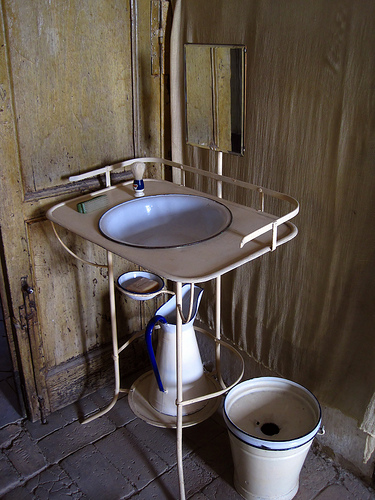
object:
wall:
[187, 1, 371, 378]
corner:
[158, 6, 196, 324]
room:
[0, 1, 375, 500]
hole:
[259, 422, 281, 437]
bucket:
[222, 376, 320, 500]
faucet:
[130, 162, 145, 198]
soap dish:
[117, 270, 165, 301]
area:
[180, 0, 373, 221]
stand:
[47, 154, 302, 495]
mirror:
[181, 43, 245, 154]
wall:
[2, 0, 175, 431]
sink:
[98, 191, 234, 245]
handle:
[140, 314, 168, 395]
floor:
[0, 363, 374, 499]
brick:
[0, 479, 37, 500]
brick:
[0, 420, 48, 474]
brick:
[23, 391, 101, 440]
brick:
[58, 441, 136, 498]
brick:
[95, 427, 168, 490]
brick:
[204, 473, 239, 500]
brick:
[37, 408, 115, 464]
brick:
[318, 465, 375, 500]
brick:
[290, 447, 340, 498]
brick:
[311, 468, 374, 499]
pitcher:
[146, 284, 211, 416]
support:
[79, 397, 120, 427]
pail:
[221, 375, 325, 499]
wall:
[184, 46, 229, 150]